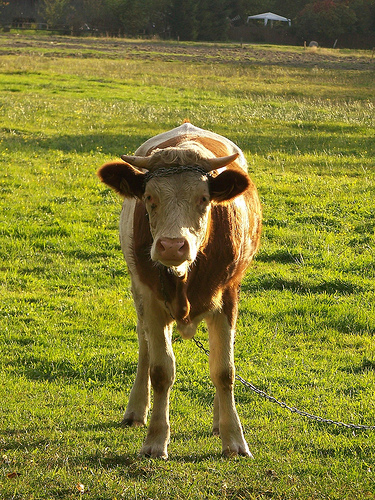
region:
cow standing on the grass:
[90, 117, 296, 455]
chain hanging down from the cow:
[159, 300, 369, 441]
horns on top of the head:
[110, 144, 232, 164]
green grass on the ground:
[0, 25, 369, 482]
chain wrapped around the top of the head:
[135, 158, 212, 175]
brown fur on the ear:
[94, 159, 147, 197]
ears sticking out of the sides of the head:
[88, 162, 254, 204]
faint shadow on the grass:
[15, 348, 227, 421]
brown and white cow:
[89, 119, 280, 472]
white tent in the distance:
[247, 8, 294, 29]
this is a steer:
[92, 109, 349, 495]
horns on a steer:
[128, 140, 245, 176]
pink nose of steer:
[148, 218, 193, 274]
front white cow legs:
[122, 311, 273, 457]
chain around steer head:
[130, 139, 217, 193]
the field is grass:
[10, 100, 368, 498]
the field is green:
[8, 98, 373, 489]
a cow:
[92, 112, 282, 462]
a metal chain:
[291, 399, 326, 430]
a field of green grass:
[25, 239, 101, 367]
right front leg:
[145, 366, 173, 465]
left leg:
[211, 358, 246, 458]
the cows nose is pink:
[157, 239, 185, 263]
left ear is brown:
[214, 163, 252, 201]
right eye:
[139, 185, 158, 209]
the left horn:
[217, 151, 241, 164]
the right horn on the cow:
[120, 151, 146, 162]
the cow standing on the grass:
[95, 117, 261, 458]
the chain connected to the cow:
[144, 211, 373, 431]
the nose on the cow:
[155, 239, 184, 260]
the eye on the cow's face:
[146, 194, 151, 200]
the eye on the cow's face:
[200, 195, 205, 201]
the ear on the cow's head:
[96, 160, 145, 198]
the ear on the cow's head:
[208, 169, 248, 205]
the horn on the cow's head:
[120, 153, 153, 169]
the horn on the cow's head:
[206, 152, 238, 170]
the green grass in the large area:
[0, 27, 373, 496]